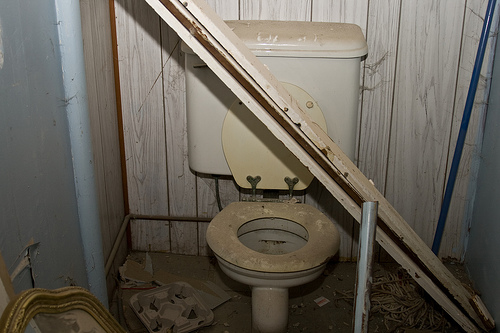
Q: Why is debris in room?
A: Under construction.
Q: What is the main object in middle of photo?
A: Commode.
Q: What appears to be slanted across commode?
A: Boards.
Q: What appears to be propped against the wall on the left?
A: Mirror.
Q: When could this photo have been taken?
A: Daylight.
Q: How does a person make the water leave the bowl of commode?
A: By flushing it.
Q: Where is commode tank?
A: Top of commode.